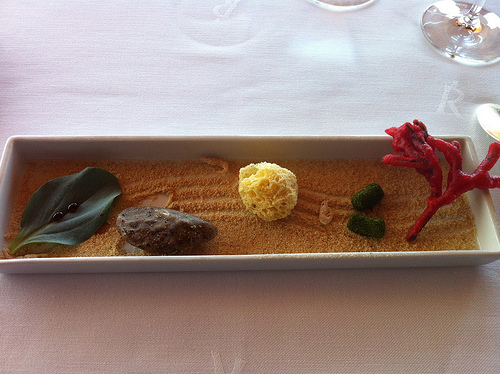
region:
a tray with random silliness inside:
[1, 127, 488, 262]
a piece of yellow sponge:
[229, 161, 300, 228]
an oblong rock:
[110, 210, 225, 248]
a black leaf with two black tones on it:
[20, 167, 127, 254]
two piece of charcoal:
[337, 184, 401, 252]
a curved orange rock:
[195, 152, 238, 184]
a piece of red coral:
[377, 119, 497, 244]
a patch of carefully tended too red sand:
[173, 163, 216, 211]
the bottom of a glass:
[411, 4, 498, 74]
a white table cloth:
[114, 22, 256, 112]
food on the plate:
[2, 144, 471, 244]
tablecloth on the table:
[103, 313, 332, 344]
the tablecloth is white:
[103, 313, 224, 355]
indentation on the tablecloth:
[150, 7, 272, 59]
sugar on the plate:
[227, 222, 267, 239]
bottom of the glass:
[395, 13, 487, 70]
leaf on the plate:
[16, 175, 96, 240]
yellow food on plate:
[212, 132, 293, 228]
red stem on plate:
[400, 130, 481, 239]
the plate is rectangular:
[17, 133, 493, 250]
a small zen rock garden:
[18, 111, 480, 309]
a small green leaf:
[24, 162, 104, 252]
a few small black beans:
[34, 201, 94, 229]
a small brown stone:
[120, 198, 197, 258]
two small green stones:
[345, 172, 390, 243]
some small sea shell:
[304, 186, 341, 234]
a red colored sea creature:
[404, 109, 489, 247]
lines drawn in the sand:
[182, 166, 222, 220]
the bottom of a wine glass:
[402, 2, 493, 63]